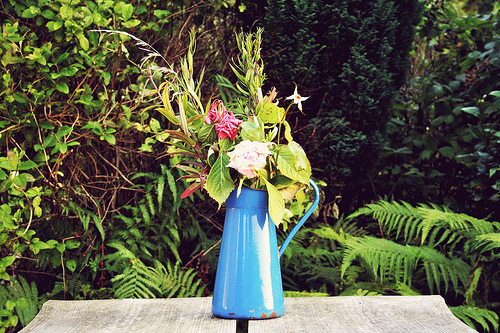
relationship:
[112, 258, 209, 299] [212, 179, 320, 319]
fern plant near can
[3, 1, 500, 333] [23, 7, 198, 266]
foliage of bush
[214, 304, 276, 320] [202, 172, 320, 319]
rust on a vase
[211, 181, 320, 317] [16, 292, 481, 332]
pitcher on a table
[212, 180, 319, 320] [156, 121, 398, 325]
pitcher used a vase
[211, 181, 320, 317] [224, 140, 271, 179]
pitcher and flower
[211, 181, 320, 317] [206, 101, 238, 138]
pitcher and flower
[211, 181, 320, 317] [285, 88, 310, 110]
pitcher and flower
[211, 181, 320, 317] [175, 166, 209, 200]
pitcher and flower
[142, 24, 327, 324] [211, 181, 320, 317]
still life with pitcher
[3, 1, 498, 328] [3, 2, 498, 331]
foliage in a garden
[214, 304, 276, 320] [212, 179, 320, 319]
rust from can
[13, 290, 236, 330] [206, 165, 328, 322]
table holding can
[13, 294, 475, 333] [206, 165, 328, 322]
table holding can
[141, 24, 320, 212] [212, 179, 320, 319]
flowers in can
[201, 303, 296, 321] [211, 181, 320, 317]
rust on pitcher